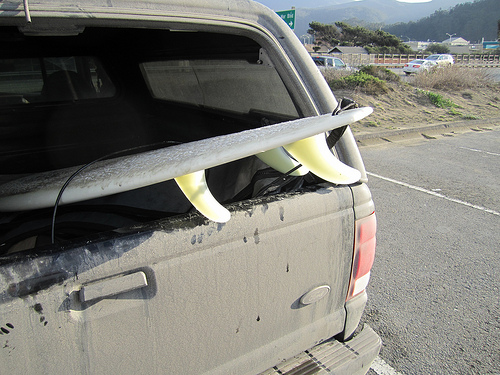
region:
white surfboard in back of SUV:
[16, 80, 383, 246]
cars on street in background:
[321, 40, 471, 88]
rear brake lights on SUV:
[330, 203, 394, 313]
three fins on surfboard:
[129, 131, 369, 236]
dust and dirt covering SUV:
[216, 210, 298, 337]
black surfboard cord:
[37, 134, 164, 247]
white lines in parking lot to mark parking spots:
[426, 125, 481, 232]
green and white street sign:
[261, 5, 301, 35]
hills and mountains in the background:
[315, 0, 459, 54]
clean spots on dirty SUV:
[10, 291, 58, 353]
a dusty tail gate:
[0, 181, 362, 373]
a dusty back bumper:
[266, 318, 388, 371]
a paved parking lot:
[336, 129, 496, 362]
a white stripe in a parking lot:
[356, 154, 487, 226]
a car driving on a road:
[401, 57, 434, 75]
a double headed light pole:
[444, 31, 459, 48]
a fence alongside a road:
[325, 49, 495, 69]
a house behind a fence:
[326, 42, 371, 59]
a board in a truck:
[4, 74, 374, 275]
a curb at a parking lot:
[355, 112, 497, 145]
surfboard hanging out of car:
[15, 83, 362, 270]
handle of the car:
[71, 260, 166, 325]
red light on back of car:
[330, 208, 392, 297]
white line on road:
[408, 162, 480, 235]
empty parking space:
[406, 133, 485, 221]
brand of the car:
[279, 272, 343, 329]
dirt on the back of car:
[176, 242, 288, 357]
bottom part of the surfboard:
[157, 154, 237, 226]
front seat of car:
[23, 61, 103, 110]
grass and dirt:
[410, 87, 454, 123]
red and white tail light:
[343, 209, 378, 305]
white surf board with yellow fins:
[2, 93, 392, 238]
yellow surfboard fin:
[281, 133, 366, 195]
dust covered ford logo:
[297, 275, 335, 310]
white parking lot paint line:
[362, 165, 497, 228]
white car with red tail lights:
[400, 56, 440, 73]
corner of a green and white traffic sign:
[272, 5, 306, 32]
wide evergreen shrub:
[306, 13, 427, 58]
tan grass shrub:
[410, 59, 497, 93]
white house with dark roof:
[443, 30, 476, 48]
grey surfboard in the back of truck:
[2, 97, 372, 209]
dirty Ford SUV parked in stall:
[1, 2, 383, 374]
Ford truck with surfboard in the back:
[1, 0, 383, 373]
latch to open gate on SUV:
[77, 270, 149, 302]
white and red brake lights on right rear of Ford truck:
[347, 212, 377, 299]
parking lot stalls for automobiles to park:
[378, 130, 498, 334]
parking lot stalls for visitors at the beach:
[1, 0, 497, 373]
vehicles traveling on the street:
[325, 52, 462, 74]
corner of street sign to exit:
[279, 6, 305, 27]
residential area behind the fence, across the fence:
[308, 26, 498, 63]